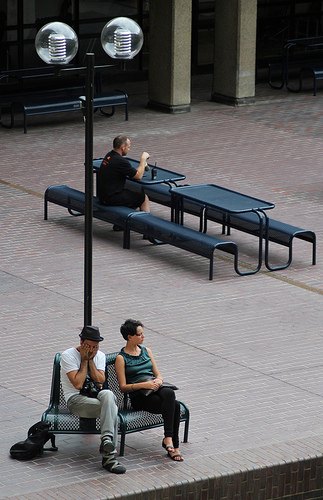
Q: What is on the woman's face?
A: Glasses.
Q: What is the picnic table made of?
A: Metal.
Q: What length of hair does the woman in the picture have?
A: Short.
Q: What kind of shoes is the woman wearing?
A: Sandals.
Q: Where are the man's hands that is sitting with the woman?
A: Over his face.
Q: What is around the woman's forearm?
A: A bracelet.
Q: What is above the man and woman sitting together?
A: Light pole.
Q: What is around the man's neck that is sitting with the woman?
A: A camera.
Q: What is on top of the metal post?
A: Lights.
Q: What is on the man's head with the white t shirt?
A: A hat.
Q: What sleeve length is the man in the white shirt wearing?
A: Short sleeves.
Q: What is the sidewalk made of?
A: Brick.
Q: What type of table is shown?
A: Picnic table.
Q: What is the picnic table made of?
A: Metal.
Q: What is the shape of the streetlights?
A: Round.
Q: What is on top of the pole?
A: Street lights.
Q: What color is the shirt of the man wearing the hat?
A: White.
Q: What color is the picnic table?
A: Black.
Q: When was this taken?
A: Daytime.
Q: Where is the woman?
A: Next to the man in the hat.